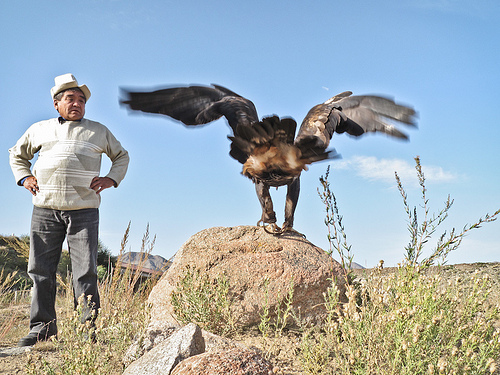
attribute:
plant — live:
[320, 227, 498, 364]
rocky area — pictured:
[113, 223, 385, 373]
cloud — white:
[326, 155, 475, 190]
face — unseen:
[243, 143, 295, 183]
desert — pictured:
[31, 259, 436, 374]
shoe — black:
[14, 325, 59, 347]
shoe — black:
[78, 319, 96, 346]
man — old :
[7, 70, 129, 342]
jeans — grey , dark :
[25, 202, 100, 333]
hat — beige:
[45, 67, 87, 112]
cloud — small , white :
[326, 147, 456, 193]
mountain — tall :
[113, 249, 173, 274]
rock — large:
[125, 221, 364, 343]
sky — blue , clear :
[3, 1, 497, 270]